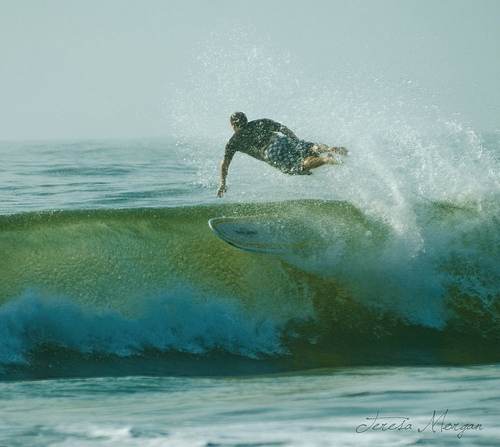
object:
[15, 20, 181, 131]
view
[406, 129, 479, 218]
sea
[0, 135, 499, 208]
area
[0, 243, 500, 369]
ocean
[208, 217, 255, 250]
edge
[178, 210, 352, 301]
bard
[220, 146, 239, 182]
arm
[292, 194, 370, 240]
wave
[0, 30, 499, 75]
cloud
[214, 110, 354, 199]
guy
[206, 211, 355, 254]
board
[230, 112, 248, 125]
helmet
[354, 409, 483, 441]
name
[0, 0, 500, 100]
sky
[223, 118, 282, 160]
shirt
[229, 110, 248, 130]
hair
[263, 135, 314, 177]
short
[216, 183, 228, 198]
hand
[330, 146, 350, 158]
leg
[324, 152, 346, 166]
foot